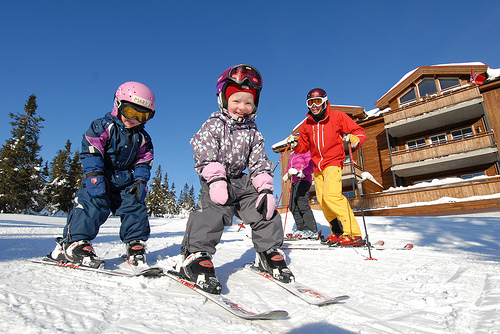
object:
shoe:
[174, 252, 222, 295]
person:
[181, 62, 293, 294]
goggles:
[227, 65, 264, 89]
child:
[287, 87, 366, 246]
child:
[56, 73, 163, 268]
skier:
[285, 89, 378, 260]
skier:
[162, 64, 351, 319]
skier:
[27, 81, 164, 276]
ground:
[375, 213, 465, 236]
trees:
[44, 139, 80, 216]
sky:
[285, 25, 384, 87]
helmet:
[304, 88, 329, 109]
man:
[280, 87, 364, 250]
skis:
[284, 230, 416, 254]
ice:
[34, 279, 177, 320]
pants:
[312, 159, 364, 239]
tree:
[0, 95, 51, 215]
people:
[48, 64, 368, 294]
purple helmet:
[213, 64, 263, 122]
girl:
[52, 81, 157, 267]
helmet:
[105, 73, 159, 126]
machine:
[165, 261, 290, 329]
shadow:
[402, 218, 484, 254]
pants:
[182, 175, 284, 254]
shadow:
[281, 319, 358, 333]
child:
[176, 63, 295, 291]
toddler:
[161, 63, 350, 319]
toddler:
[29, 80, 166, 277]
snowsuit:
[62, 112, 154, 239]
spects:
[305, 95, 327, 109]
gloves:
[207, 179, 279, 221]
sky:
[1, 0, 500, 60]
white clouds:
[202, 19, 273, 44]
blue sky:
[2, 0, 498, 183]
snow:
[0, 210, 499, 331]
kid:
[183, 67, 295, 287]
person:
[294, 87, 366, 247]